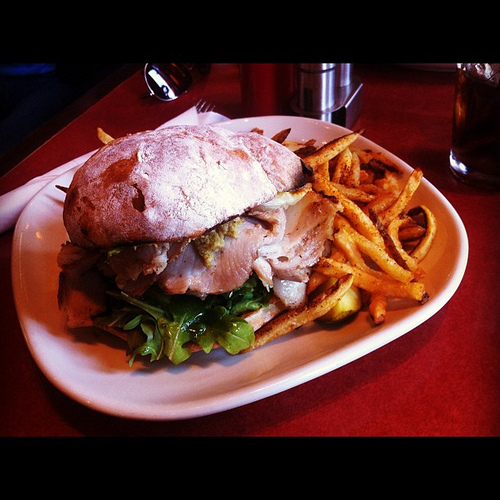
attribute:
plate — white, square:
[13, 113, 473, 424]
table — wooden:
[1, 65, 500, 436]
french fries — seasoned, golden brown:
[242, 124, 438, 354]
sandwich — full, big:
[62, 124, 336, 368]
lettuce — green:
[93, 279, 273, 367]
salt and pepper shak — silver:
[285, 64, 363, 130]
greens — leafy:
[90, 289, 268, 365]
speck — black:
[321, 302, 325, 310]